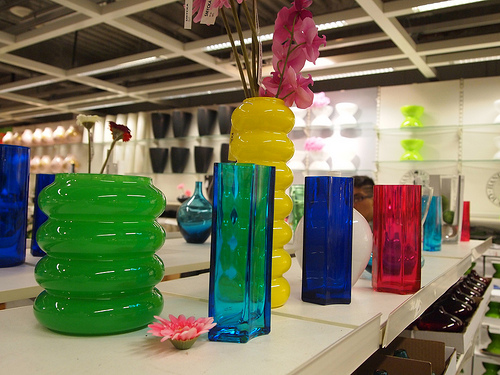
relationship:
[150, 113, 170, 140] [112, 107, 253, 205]
vase on wall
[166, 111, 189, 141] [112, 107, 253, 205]
vase on wall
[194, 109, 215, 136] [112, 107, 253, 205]
vase on wall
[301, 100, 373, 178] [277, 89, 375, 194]
vases on wall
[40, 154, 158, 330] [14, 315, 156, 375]
vase on counter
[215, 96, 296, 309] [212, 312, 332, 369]
vase on counter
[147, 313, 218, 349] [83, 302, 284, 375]
flower on counter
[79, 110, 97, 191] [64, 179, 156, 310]
flower in vase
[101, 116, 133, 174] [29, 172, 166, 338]
flower in vase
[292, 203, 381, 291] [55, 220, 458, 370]
vase on counter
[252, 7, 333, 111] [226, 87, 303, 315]
flower in vase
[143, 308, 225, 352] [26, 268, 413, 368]
flower on shelf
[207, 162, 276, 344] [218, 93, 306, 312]
glass vase next to vase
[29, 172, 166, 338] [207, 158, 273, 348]
vase next to vase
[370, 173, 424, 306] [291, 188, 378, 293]
vase next to vase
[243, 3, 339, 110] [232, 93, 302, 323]
flower next to vase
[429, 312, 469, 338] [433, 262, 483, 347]
light bulb in drawer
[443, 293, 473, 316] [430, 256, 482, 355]
light bulb in drawer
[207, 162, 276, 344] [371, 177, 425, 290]
glass vase next to vase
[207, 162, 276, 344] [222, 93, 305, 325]
glass vase next to vase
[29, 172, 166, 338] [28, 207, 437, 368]
vase on table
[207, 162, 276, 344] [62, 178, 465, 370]
glass vase on table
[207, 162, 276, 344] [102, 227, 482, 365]
glass vase on table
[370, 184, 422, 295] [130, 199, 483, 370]
vase on table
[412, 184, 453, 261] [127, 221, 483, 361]
vase on table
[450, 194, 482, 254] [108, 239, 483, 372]
vase on table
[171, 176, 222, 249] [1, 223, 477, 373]
vase on table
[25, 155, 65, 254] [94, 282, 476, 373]
vase on table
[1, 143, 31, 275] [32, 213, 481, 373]
vase on table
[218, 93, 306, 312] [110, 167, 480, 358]
vase on table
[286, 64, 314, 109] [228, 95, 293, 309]
flower blooming in vase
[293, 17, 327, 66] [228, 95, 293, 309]
flower blooming in vase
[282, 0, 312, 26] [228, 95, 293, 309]
flower blooming in vase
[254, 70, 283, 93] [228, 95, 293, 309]
flower blooming in vase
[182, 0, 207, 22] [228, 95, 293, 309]
flower blooming in vase